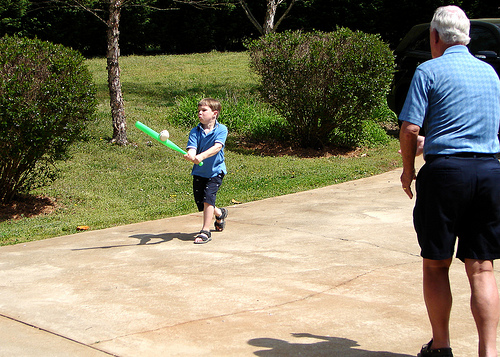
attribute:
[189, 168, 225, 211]
shorts — blue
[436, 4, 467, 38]
hair — short, cut, gray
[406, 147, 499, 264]
shorts — blue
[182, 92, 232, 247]
boy — little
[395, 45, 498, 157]
shirt — blue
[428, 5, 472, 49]
hair — silver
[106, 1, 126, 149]
tree trunk — rough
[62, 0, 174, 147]
tree — rough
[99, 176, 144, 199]
grass — green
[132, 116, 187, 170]
bat — green, baseball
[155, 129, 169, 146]
baseball — white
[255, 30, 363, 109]
bush — large, green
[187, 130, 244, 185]
shirt — blue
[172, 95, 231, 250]
boy — little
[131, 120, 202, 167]
bat — green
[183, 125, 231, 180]
shirt — blue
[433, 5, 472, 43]
hair — gray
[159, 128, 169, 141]
ball — white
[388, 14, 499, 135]
car — black